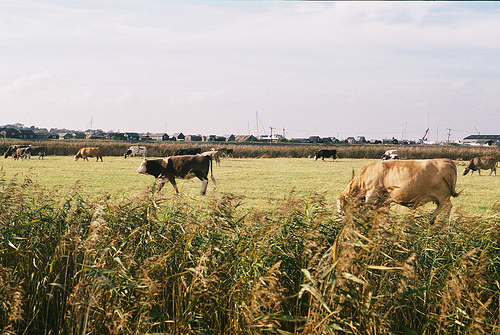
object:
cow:
[73, 146, 104, 162]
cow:
[305, 147, 339, 161]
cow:
[460, 156, 497, 178]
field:
[1, 158, 500, 334]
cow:
[133, 155, 216, 196]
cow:
[335, 157, 466, 223]